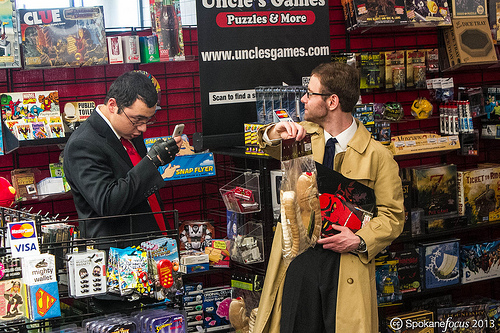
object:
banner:
[193, 0, 331, 151]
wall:
[0, 0, 498, 205]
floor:
[357, 148, 394, 192]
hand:
[268, 121, 306, 142]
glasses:
[121, 105, 158, 127]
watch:
[358, 238, 366, 253]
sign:
[194, 0, 335, 139]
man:
[255, 62, 405, 333]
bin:
[219, 171, 262, 214]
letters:
[201, 50, 233, 61]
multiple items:
[65, 220, 231, 299]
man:
[60, 70, 183, 253]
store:
[0, 0, 499, 333]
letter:
[226, 14, 234, 25]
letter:
[234, 50, 249, 60]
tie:
[119, 135, 167, 235]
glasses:
[305, 87, 332, 99]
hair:
[310, 62, 373, 116]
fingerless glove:
[147, 138, 180, 167]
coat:
[251, 116, 405, 333]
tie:
[322, 137, 339, 171]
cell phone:
[172, 124, 185, 138]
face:
[117, 103, 157, 140]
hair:
[103, 71, 158, 115]